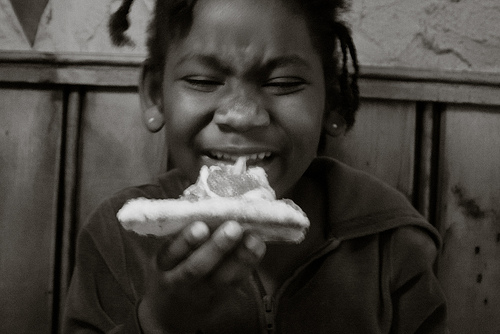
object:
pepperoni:
[205, 165, 262, 198]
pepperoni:
[180, 184, 211, 202]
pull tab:
[260, 290, 278, 331]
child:
[57, 0, 450, 330]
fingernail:
[188, 220, 212, 241]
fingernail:
[221, 218, 246, 243]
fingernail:
[243, 232, 262, 252]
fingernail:
[253, 240, 269, 258]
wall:
[0, 0, 499, 332]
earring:
[144, 115, 157, 131]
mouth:
[193, 142, 285, 172]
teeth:
[257, 151, 266, 160]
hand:
[117, 219, 268, 334]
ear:
[322, 68, 351, 141]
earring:
[328, 122, 340, 136]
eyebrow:
[174, 48, 236, 77]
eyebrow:
[258, 51, 315, 75]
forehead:
[173, 3, 318, 63]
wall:
[2, 0, 499, 72]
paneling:
[0, 51, 498, 331]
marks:
[468, 242, 486, 256]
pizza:
[115, 156, 311, 246]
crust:
[117, 196, 315, 246]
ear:
[138, 56, 168, 135]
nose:
[212, 78, 273, 134]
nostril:
[215, 122, 237, 133]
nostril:
[249, 121, 269, 131]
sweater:
[60, 155, 448, 333]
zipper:
[241, 236, 341, 332]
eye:
[175, 70, 227, 94]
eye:
[262, 69, 312, 97]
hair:
[106, 0, 363, 136]